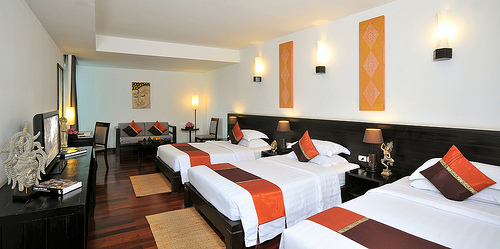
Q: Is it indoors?
A: Yes, it is indoors.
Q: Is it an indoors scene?
A: Yes, it is indoors.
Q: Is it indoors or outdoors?
A: It is indoors.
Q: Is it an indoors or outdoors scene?
A: It is indoors.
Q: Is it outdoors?
A: No, it is indoors.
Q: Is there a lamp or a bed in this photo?
A: Yes, there is a lamp.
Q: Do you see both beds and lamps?
A: Yes, there are both a lamp and a bed.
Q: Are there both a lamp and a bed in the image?
A: Yes, there are both a lamp and a bed.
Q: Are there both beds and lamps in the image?
A: Yes, there are both a lamp and a bed.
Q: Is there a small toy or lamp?
A: Yes, there is a small lamp.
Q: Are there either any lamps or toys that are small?
A: Yes, the lamp is small.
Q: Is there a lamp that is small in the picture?
A: Yes, there is a small lamp.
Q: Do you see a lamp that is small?
A: Yes, there is a lamp that is small.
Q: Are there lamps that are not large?
A: Yes, there is a small lamp.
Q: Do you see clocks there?
A: No, there are no clocks.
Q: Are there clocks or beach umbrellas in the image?
A: No, there are no clocks or beach umbrellas.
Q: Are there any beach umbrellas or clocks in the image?
A: No, there are no clocks or beach umbrellas.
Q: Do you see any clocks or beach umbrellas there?
A: No, there are no clocks or beach umbrellas.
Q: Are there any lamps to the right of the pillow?
A: Yes, there is a lamp to the right of the pillow.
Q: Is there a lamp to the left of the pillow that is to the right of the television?
A: No, the lamp is to the right of the pillow.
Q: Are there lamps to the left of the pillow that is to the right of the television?
A: No, the lamp is to the right of the pillow.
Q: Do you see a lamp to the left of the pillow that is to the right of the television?
A: No, the lamp is to the right of the pillow.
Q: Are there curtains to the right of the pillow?
A: No, there is a lamp to the right of the pillow.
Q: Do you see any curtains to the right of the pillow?
A: No, there is a lamp to the right of the pillow.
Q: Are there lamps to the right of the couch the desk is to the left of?
A: Yes, there is a lamp to the right of the couch.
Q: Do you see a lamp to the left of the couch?
A: No, the lamp is to the right of the couch.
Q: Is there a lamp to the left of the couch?
A: No, the lamp is to the right of the couch.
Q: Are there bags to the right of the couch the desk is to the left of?
A: No, there is a lamp to the right of the couch.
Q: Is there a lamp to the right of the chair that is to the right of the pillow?
A: Yes, there is a lamp to the right of the chair.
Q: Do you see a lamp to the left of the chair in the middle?
A: No, the lamp is to the right of the chair.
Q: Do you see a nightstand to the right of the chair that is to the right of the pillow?
A: No, there is a lamp to the right of the chair.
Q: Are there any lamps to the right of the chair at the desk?
A: Yes, there is a lamp to the right of the chair.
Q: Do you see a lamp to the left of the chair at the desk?
A: No, the lamp is to the right of the chair.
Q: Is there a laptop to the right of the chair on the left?
A: No, there is a lamp to the right of the chair.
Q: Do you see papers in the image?
A: No, there are no papers.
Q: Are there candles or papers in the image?
A: No, there are no papers or candles.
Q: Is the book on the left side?
A: Yes, the book is on the left of the image.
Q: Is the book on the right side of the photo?
A: No, the book is on the left of the image.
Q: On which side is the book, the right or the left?
A: The book is on the left of the image.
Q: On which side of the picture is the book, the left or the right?
A: The book is on the left of the image.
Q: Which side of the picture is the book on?
A: The book is on the left of the image.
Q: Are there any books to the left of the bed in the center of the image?
A: Yes, there is a book to the left of the bed.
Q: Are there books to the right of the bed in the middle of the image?
A: No, the book is to the left of the bed.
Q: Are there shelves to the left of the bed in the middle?
A: No, there is a book to the left of the bed.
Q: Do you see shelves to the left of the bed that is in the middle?
A: No, there is a book to the left of the bed.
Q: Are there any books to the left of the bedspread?
A: Yes, there is a book to the left of the bedspread.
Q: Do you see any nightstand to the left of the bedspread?
A: No, there is a book to the left of the bedspread.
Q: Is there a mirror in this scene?
A: No, there are no mirrors.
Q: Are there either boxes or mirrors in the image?
A: No, there are no mirrors or boxes.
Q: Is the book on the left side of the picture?
A: Yes, the book is on the left of the image.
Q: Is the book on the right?
A: No, the book is on the left of the image.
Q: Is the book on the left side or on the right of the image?
A: The book is on the left of the image.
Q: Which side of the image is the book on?
A: The book is on the left of the image.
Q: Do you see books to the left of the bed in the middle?
A: Yes, there is a book to the left of the bed.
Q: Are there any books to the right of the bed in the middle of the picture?
A: No, the book is to the left of the bed.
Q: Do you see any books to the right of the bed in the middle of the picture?
A: No, the book is to the left of the bed.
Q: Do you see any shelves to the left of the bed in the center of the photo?
A: No, there is a book to the left of the bed.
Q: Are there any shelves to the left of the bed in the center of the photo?
A: No, there is a book to the left of the bed.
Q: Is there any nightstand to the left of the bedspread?
A: No, there is a book to the left of the bedspread.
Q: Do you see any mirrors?
A: No, there are no mirrors.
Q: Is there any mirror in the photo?
A: No, there are no mirrors.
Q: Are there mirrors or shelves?
A: No, there are no mirrors or shelves.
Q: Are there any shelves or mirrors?
A: No, there are no mirrors or shelves.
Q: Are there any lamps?
A: Yes, there is a lamp.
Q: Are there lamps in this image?
A: Yes, there is a lamp.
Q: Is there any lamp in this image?
A: Yes, there is a lamp.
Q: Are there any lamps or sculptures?
A: Yes, there is a lamp.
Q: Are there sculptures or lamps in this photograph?
A: Yes, there is a lamp.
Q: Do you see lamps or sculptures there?
A: Yes, there is a lamp.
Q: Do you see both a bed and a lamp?
A: Yes, there are both a lamp and a bed.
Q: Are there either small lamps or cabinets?
A: Yes, there is a small lamp.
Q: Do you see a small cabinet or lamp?
A: Yes, there is a small lamp.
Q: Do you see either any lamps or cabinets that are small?
A: Yes, the lamp is small.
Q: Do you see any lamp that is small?
A: Yes, there is a small lamp.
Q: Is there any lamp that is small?
A: Yes, there is a lamp that is small.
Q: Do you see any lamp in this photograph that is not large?
A: Yes, there is a small lamp.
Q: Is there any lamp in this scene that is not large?
A: Yes, there is a small lamp.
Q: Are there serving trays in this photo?
A: No, there are no serving trays.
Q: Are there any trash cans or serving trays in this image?
A: No, there are no serving trays or trash cans.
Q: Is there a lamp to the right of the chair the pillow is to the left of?
A: Yes, there is a lamp to the right of the chair.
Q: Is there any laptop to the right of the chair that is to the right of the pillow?
A: No, there is a lamp to the right of the chair.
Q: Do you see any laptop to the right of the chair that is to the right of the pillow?
A: No, there is a lamp to the right of the chair.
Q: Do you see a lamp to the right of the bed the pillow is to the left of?
A: Yes, there is a lamp to the right of the bed.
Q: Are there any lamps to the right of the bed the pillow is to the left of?
A: Yes, there is a lamp to the right of the bed.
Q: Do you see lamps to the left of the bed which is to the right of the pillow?
A: No, the lamp is to the right of the bed.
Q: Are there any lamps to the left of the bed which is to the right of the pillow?
A: No, the lamp is to the right of the bed.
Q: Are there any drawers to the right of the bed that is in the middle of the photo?
A: No, there is a lamp to the right of the bed.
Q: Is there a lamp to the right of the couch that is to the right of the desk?
A: Yes, there is a lamp to the right of the couch.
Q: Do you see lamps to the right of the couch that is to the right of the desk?
A: Yes, there is a lamp to the right of the couch.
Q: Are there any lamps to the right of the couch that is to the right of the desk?
A: Yes, there is a lamp to the right of the couch.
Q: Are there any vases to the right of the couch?
A: No, there is a lamp to the right of the couch.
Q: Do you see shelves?
A: No, there are no shelves.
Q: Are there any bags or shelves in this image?
A: No, there are no shelves or bags.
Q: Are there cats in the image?
A: No, there are no cats.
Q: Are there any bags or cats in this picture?
A: No, there are no cats or bags.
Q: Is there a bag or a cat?
A: No, there are no cats or bags.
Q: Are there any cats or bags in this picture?
A: No, there are no cats or bags.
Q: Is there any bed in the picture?
A: Yes, there is a bed.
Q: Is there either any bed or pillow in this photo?
A: Yes, there is a bed.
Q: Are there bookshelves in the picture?
A: No, there are no bookshelves.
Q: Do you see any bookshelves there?
A: No, there are no bookshelves.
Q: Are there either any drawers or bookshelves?
A: No, there are no bookshelves or drawers.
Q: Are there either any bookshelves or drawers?
A: No, there are no bookshelves or drawers.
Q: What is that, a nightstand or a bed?
A: That is a bed.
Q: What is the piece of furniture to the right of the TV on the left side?
A: The piece of furniture is a bed.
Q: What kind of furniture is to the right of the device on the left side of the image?
A: The piece of furniture is a bed.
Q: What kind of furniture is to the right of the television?
A: The piece of furniture is a bed.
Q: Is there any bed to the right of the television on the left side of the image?
A: Yes, there is a bed to the right of the television.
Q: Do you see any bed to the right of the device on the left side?
A: Yes, there is a bed to the right of the television.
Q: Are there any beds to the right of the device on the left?
A: Yes, there is a bed to the right of the television.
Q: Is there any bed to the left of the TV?
A: No, the bed is to the right of the TV.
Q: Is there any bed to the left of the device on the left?
A: No, the bed is to the right of the TV.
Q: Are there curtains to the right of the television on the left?
A: No, there is a bed to the right of the television.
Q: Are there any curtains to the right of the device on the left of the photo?
A: No, there is a bed to the right of the television.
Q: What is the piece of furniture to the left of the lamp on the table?
A: The piece of furniture is a bed.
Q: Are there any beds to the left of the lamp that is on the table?
A: Yes, there is a bed to the left of the lamp.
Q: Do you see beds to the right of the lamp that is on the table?
A: No, the bed is to the left of the lamp.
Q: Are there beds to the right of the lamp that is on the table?
A: No, the bed is to the left of the lamp.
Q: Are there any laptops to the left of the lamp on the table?
A: No, there is a bed to the left of the lamp.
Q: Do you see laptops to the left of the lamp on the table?
A: No, there is a bed to the left of the lamp.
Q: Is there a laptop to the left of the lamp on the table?
A: No, there is a bed to the left of the lamp.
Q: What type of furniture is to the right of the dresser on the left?
A: The piece of furniture is a bed.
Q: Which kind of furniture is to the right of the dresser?
A: The piece of furniture is a bed.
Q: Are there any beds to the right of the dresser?
A: Yes, there is a bed to the right of the dresser.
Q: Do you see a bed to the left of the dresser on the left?
A: No, the bed is to the right of the dresser.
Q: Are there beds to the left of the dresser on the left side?
A: No, the bed is to the right of the dresser.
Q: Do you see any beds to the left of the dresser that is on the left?
A: No, the bed is to the right of the dresser.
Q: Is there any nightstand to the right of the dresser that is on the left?
A: No, there is a bed to the right of the dresser.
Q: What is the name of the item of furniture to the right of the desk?
A: The piece of furniture is a bed.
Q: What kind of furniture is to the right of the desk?
A: The piece of furniture is a bed.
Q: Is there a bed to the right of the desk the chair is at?
A: Yes, there is a bed to the right of the desk.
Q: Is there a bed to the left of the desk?
A: No, the bed is to the right of the desk.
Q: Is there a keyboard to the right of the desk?
A: No, there is a bed to the right of the desk.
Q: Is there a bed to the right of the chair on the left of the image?
A: Yes, there is a bed to the right of the chair.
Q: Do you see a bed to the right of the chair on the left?
A: Yes, there is a bed to the right of the chair.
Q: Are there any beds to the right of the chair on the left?
A: Yes, there is a bed to the right of the chair.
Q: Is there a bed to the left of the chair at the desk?
A: No, the bed is to the right of the chair.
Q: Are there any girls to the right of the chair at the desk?
A: No, there is a bed to the right of the chair.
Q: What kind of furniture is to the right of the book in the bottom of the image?
A: The piece of furniture is a bed.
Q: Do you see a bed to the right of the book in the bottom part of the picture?
A: Yes, there is a bed to the right of the book.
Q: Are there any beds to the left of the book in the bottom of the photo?
A: No, the bed is to the right of the book.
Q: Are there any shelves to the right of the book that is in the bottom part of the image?
A: No, there is a bed to the right of the book.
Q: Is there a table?
A: Yes, there is a table.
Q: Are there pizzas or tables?
A: Yes, there is a table.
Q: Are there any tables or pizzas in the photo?
A: Yes, there is a table.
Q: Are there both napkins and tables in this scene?
A: No, there is a table but no napkins.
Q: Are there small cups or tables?
A: Yes, there is a small table.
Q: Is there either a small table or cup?
A: Yes, there is a small table.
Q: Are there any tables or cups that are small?
A: Yes, the table is small.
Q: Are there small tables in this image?
A: Yes, there is a small table.